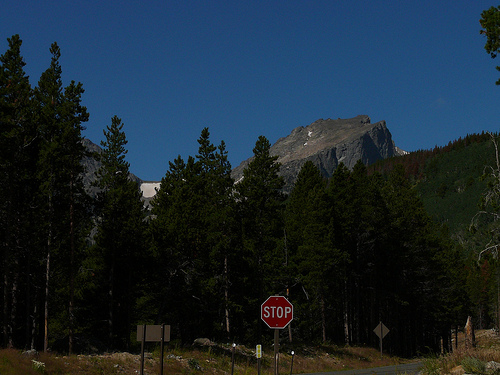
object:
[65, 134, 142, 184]
mountain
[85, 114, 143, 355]
tree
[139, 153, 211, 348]
tree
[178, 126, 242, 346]
tree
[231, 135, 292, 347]
tree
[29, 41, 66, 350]
tree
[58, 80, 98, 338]
tree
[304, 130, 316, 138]
white snow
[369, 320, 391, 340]
sign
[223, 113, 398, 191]
rock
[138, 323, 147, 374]
metal post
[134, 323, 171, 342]
sign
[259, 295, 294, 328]
sign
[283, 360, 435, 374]
road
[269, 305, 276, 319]
letter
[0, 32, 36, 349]
pine trees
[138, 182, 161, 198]
snow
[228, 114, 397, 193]
mountain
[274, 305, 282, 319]
letters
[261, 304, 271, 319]
s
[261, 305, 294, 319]
stop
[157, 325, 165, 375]
poles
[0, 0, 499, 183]
cloud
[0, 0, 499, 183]
sky